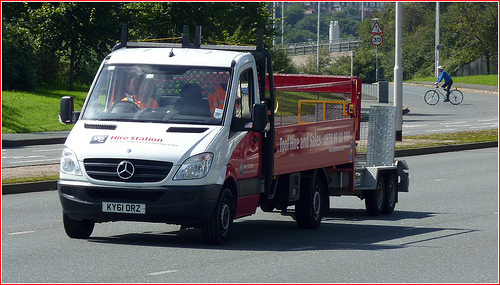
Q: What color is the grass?
A: Green.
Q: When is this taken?
A: Daytime.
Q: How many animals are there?
A: 0.